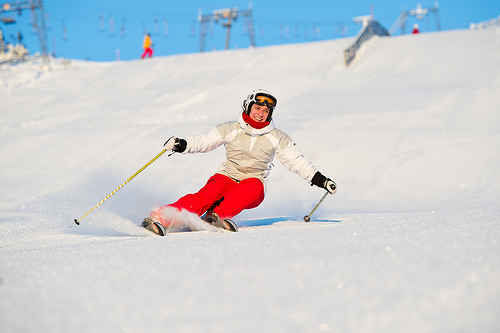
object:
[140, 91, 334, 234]
woman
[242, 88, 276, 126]
helmet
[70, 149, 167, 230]
ski pole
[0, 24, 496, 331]
snow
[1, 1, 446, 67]
ski lift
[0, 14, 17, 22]
chairs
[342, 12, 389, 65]
fence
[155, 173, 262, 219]
pants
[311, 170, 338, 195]
glove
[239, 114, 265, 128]
scarf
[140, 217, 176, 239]
skis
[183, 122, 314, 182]
jacket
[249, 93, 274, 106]
goggles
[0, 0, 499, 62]
sky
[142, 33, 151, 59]
person